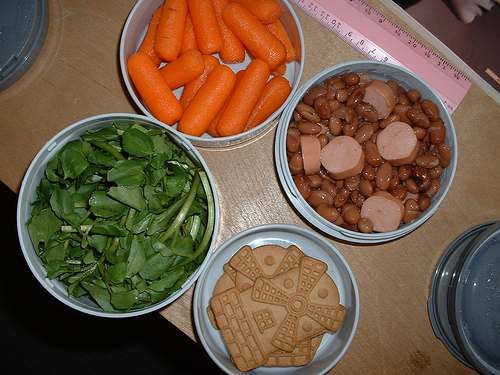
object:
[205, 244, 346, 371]
cookies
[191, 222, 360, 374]
plate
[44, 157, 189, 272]
greens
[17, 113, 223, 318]
container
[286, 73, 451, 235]
food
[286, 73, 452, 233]
beans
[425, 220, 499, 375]
plate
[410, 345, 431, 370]
water spot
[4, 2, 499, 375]
table top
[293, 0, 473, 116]
ruler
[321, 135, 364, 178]
frank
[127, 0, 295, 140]
carrots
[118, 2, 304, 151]
bowl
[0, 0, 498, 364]
table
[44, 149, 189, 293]
veggie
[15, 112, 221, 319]
bowl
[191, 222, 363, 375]
bowl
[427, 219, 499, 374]
blue container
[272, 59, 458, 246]
bowl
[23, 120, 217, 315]
food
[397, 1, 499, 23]
magazine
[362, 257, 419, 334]
wood grain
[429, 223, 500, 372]
lids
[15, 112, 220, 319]
dish